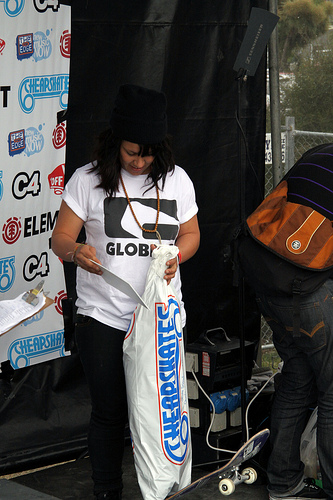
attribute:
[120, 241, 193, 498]
bag — white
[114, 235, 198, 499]
bag — white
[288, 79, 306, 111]
ground — brown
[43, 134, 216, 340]
shirt — white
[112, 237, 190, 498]
bag — white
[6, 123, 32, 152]
emblem — electrical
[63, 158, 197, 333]
shirt — white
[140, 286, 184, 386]
bag — white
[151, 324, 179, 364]
letters — blue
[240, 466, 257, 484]
wheels — white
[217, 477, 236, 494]
wheels — white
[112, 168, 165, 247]
necklace — brown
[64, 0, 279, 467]
equipment — electrical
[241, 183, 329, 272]
bag — black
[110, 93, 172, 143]
hat — black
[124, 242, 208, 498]
bag — white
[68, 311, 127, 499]
pants — black